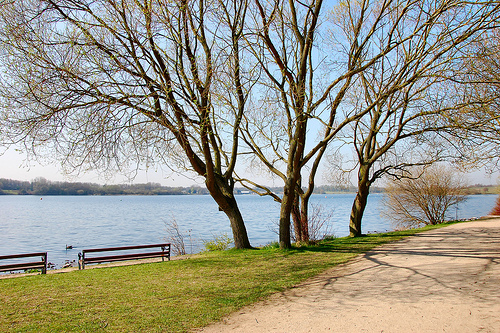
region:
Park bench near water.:
[76, 245, 191, 258]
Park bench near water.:
[8, 245, 60, 278]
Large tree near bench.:
[173, 86, 253, 236]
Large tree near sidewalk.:
[347, 124, 374, 244]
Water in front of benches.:
[60, 197, 189, 227]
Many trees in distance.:
[16, 177, 79, 189]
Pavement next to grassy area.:
[378, 249, 465, 326]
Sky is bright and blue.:
[239, 31, 377, 88]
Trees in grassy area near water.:
[278, 90, 313, 249]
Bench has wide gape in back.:
[86, 247, 171, 258]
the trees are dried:
[170, 17, 400, 138]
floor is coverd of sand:
[371, 279, 478, 330]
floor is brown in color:
[391, 289, 496, 328]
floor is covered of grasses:
[128, 275, 183, 330]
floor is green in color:
[102, 282, 173, 325]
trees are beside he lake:
[202, 151, 397, 229]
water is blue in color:
[118, 190, 178, 232]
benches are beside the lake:
[15, 226, 162, 274]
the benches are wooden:
[87, 244, 183, 264]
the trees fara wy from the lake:
[49, 172, 98, 194]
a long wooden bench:
[75, 240, 170, 267]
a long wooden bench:
[2, 251, 48, 277]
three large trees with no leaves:
[1, 1, 498, 242]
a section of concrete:
[180, 220, 498, 332]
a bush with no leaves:
[388, 168, 468, 223]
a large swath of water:
[0, 192, 498, 278]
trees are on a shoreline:
[3, 178, 206, 194]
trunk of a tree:
[193, 160, 252, 252]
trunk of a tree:
[277, 156, 298, 243]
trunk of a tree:
[351, 163, 372, 237]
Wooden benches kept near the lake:
[8, 230, 174, 272]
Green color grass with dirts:
[84, 251, 324, 315]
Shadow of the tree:
[326, 222, 497, 307]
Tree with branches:
[88, 8, 453, 147]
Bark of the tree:
[225, 210, 249, 238]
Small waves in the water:
[27, 192, 141, 224]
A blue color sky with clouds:
[230, 11, 430, 79]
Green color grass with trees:
[188, 104, 380, 277]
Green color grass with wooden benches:
[3, 223, 200, 306]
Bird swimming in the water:
[61, 240, 74, 252]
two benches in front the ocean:
[0, 216, 176, 286]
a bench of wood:
[76, 237, 177, 271]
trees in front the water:
[3, 5, 498, 254]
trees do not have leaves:
[3, 4, 499, 249]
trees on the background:
[3, 173, 499, 205]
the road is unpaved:
[211, 212, 498, 332]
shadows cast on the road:
[304, 223, 499, 300]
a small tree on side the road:
[384, 154, 465, 234]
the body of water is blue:
[5, 189, 470, 254]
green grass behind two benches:
[0, 230, 201, 329]